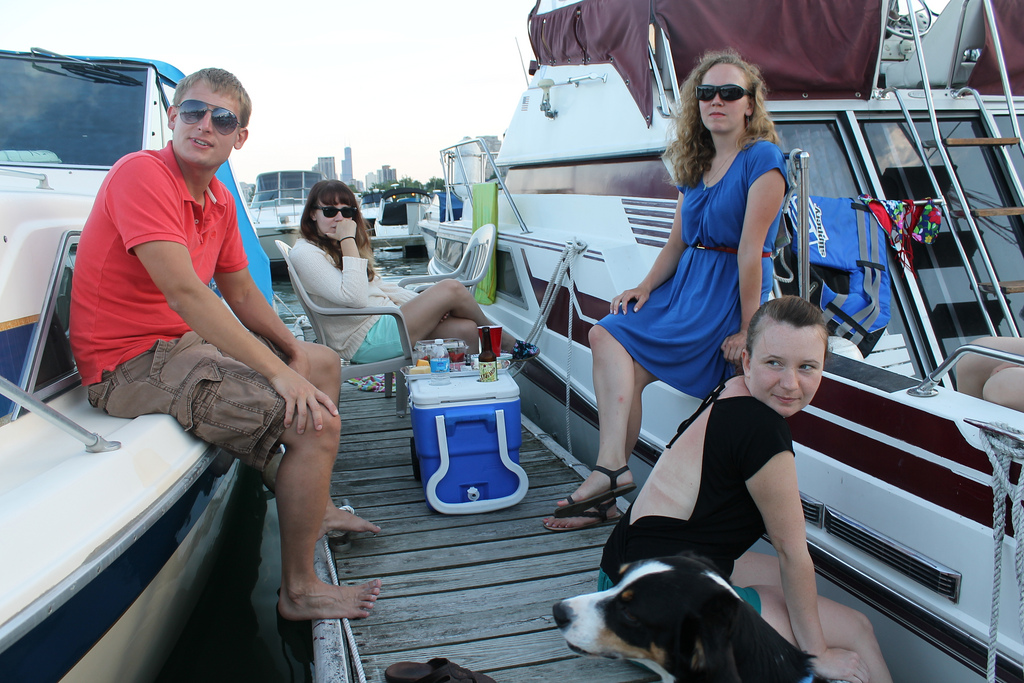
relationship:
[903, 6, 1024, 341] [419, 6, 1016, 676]
ladder on boat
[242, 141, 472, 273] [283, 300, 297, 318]
boats in water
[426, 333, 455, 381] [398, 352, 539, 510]
bottle in box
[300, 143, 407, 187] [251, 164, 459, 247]
buildings behind boats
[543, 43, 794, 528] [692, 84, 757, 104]
woman wearing eye glass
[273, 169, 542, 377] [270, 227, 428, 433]
woman sitting chair